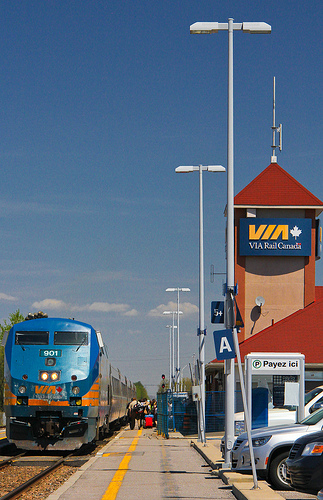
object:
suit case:
[145, 417, 152, 427]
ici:
[288, 360, 298, 367]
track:
[2, 475, 39, 499]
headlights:
[51, 373, 58, 381]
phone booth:
[170, 392, 189, 432]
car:
[229, 406, 323, 493]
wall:
[243, 262, 303, 299]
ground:
[111, 451, 220, 500]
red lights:
[162, 374, 165, 378]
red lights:
[72, 375, 77, 380]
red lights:
[23, 374, 28, 379]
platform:
[45, 415, 239, 497]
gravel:
[0, 463, 4, 476]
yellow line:
[97, 467, 128, 498]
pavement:
[42, 416, 243, 498]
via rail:
[248, 241, 278, 250]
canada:
[277, 242, 301, 250]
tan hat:
[244, 352, 304, 437]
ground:
[118, 426, 131, 440]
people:
[128, 399, 140, 416]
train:
[3, 311, 137, 454]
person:
[151, 398, 156, 427]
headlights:
[41, 372, 48, 380]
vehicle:
[287, 423, 323, 495]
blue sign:
[213, 329, 235, 361]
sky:
[0, 0, 190, 274]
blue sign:
[239, 218, 312, 257]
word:
[264, 361, 287, 369]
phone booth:
[244, 353, 305, 437]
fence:
[156, 391, 167, 438]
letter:
[219, 336, 232, 353]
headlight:
[72, 386, 79, 394]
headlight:
[19, 386, 26, 394]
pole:
[172, 313, 174, 393]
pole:
[177, 290, 179, 395]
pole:
[169, 327, 171, 392]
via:
[248, 224, 288, 241]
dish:
[255, 296, 265, 307]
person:
[130, 398, 135, 430]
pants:
[130, 417, 135, 430]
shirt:
[128, 400, 137, 410]